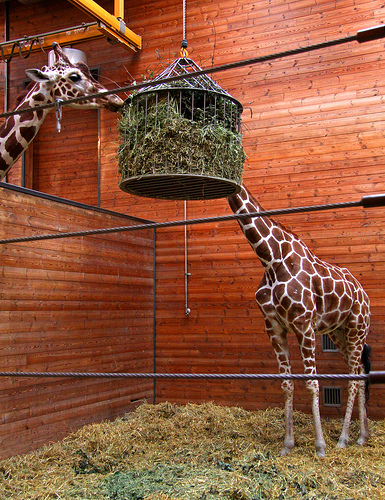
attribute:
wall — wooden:
[0, 191, 156, 401]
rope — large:
[160, 12, 197, 66]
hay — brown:
[133, 409, 271, 499]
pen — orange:
[17, 17, 377, 437]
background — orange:
[276, 79, 376, 201]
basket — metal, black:
[107, 51, 262, 209]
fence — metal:
[3, 21, 365, 117]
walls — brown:
[59, 240, 135, 320]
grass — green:
[133, 90, 235, 164]